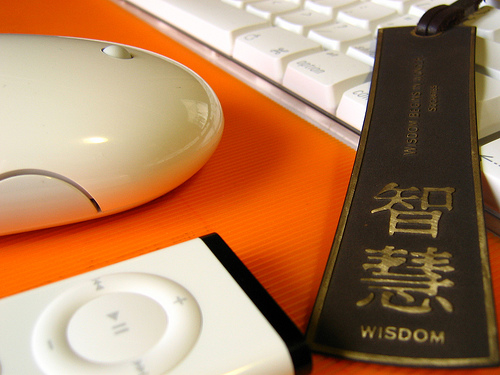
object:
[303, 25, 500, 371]
bookmark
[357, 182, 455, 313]
character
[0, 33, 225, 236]
mouse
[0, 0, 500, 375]
pad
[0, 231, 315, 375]
remote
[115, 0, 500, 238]
keyboard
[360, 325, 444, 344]
wisdom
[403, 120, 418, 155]
wisdom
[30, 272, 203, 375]
volume control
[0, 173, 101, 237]
button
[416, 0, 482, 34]
clip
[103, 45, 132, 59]
clicker